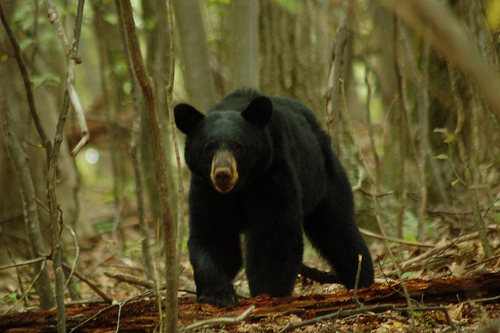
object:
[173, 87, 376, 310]
bear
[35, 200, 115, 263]
branch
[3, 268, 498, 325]
log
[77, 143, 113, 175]
camera glare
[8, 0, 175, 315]
trees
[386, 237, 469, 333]
ground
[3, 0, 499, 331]
forest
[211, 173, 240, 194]
mouth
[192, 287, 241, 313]
claws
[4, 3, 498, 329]
woods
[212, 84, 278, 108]
muscle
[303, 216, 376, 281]
leg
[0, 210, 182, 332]
weeds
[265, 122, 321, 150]
fur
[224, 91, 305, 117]
back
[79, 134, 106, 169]
glare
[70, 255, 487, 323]
twigs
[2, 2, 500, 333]
camera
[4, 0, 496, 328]
field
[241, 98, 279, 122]
ear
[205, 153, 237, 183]
nose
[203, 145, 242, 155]
eyes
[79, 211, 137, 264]
leaves